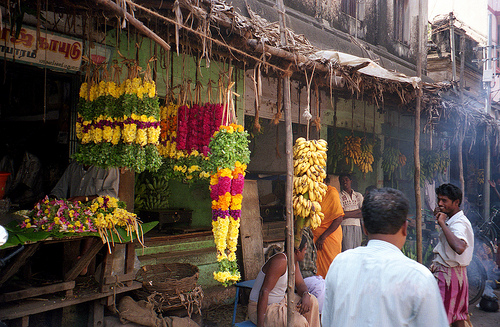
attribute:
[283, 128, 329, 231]
banana — hanging, yellow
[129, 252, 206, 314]
basket — woven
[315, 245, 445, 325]
shirt — white, worn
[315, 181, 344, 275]
dress — orange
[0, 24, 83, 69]
sign — red, in foreign language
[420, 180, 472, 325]
man — smiling, raising arms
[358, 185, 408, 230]
hair — black, dark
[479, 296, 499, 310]
pot — small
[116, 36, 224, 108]
wall — green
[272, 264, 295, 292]
chest — black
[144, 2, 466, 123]
roof — wood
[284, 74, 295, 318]
pole — wooden